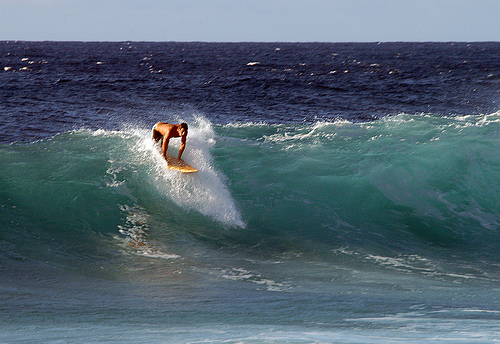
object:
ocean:
[14, 47, 497, 311]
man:
[153, 120, 184, 164]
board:
[163, 154, 198, 172]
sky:
[0, 3, 499, 43]